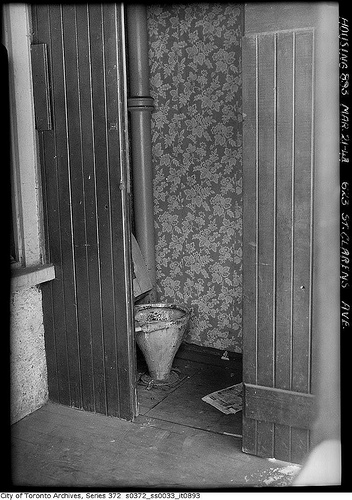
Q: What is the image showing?
A: It is showing a bathroom.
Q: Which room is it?
A: It is a bathroom.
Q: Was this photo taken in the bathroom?
A: Yes, it was taken in the bathroom.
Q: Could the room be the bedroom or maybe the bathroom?
A: It is the bathroom.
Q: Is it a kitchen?
A: No, it is a bathroom.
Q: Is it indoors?
A: Yes, it is indoors.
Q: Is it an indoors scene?
A: Yes, it is indoors.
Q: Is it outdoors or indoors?
A: It is indoors.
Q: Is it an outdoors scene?
A: No, it is indoors.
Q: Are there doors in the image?
A: Yes, there is a door.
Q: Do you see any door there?
A: Yes, there is a door.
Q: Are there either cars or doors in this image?
A: Yes, there is a door.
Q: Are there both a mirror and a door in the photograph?
A: No, there is a door but no mirrors.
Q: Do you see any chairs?
A: No, there are no chairs.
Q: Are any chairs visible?
A: No, there are no chairs.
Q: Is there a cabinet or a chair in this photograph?
A: No, there are no chairs or cabinets.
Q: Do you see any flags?
A: No, there are no flags.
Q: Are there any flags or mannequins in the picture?
A: No, there are no flags or mannequins.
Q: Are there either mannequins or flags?
A: No, there are no flags or mannequins.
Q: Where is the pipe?
A: The pipe is in the bathroom.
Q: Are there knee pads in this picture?
A: No, there are no knee pads.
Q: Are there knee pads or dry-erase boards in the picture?
A: No, there are no knee pads or dry-erase boards.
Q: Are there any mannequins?
A: No, there are no mannequins.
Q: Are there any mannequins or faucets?
A: No, there are no mannequins or faucets.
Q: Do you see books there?
A: No, there are no books.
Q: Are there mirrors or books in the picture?
A: No, there are no books or mirrors.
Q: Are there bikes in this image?
A: No, there are no bikes.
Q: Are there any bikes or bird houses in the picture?
A: No, there are no bikes or bird houses.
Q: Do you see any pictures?
A: No, there are no pictures.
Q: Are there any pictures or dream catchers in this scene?
A: No, there are no pictures or dream catchers.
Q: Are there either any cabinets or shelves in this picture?
A: No, there are no cabinets or shelves.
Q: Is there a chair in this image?
A: No, there are no chairs.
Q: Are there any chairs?
A: No, there are no chairs.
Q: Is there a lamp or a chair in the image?
A: No, there are no chairs or lamps.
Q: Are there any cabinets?
A: No, there are no cabinets.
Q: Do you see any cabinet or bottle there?
A: No, there are no cabinets or bottles.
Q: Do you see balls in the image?
A: No, there are no balls.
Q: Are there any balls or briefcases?
A: No, there are no balls or briefcases.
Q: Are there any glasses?
A: No, there are no glasses.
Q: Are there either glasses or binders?
A: No, there are no glasses or binders.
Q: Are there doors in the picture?
A: Yes, there is a door.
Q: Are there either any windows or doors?
A: Yes, there is a door.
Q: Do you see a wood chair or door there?
A: Yes, there is a wood door.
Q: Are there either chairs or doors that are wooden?
A: Yes, the door is wooden.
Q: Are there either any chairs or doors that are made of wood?
A: Yes, the door is made of wood.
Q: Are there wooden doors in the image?
A: Yes, there is a wood door.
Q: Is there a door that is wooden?
A: Yes, there is a door that is wooden.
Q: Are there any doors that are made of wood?
A: Yes, there is a door that is made of wood.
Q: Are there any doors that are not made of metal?
A: Yes, there is a door that is made of wood.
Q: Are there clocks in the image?
A: No, there are no clocks.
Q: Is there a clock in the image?
A: No, there are no clocks.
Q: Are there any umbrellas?
A: No, there are no umbrellas.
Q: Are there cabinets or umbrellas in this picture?
A: No, there are no umbrellas or cabinets.